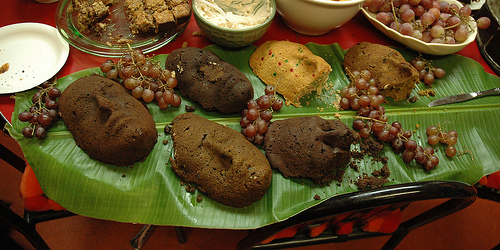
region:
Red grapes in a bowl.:
[377, 0, 489, 62]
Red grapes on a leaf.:
[350, 92, 498, 188]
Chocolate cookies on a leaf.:
[266, 110, 355, 205]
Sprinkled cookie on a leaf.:
[236, 30, 351, 114]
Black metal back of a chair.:
[256, 170, 493, 247]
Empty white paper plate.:
[3, 6, 85, 140]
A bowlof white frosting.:
[181, 1, 276, 47]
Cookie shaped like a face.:
[41, 68, 169, 187]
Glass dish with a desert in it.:
[63, 0, 184, 58]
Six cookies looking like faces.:
[52, 30, 425, 231]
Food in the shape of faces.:
[14, 36, 402, 246]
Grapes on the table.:
[60, 22, 255, 159]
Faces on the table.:
[57, 37, 429, 204]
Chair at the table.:
[160, 107, 498, 241]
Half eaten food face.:
[246, 32, 363, 121]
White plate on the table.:
[0, 12, 91, 105]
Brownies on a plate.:
[51, 2, 251, 72]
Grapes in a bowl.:
[365, 7, 471, 72]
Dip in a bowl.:
[187, 3, 300, 42]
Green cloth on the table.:
[1, 64, 498, 246]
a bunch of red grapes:
[341, 71, 406, 136]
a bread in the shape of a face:
[269, 119, 354, 181]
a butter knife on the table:
[426, 86, 498, 109]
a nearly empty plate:
[0, 22, 71, 94]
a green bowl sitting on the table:
[192, 1, 278, 47]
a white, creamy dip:
[196, 0, 273, 27]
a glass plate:
[54, 0, 191, 57]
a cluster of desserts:
[123, 0, 193, 39]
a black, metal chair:
[239, 180, 476, 249]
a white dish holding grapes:
[361, 0, 481, 57]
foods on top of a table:
[23, 5, 473, 210]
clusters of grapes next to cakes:
[42, 55, 332, 150]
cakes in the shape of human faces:
[65, 37, 351, 192]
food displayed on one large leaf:
[31, 32, 476, 197]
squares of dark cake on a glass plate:
[65, 0, 185, 52]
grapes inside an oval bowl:
[365, 1, 480, 48]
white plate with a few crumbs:
[0, 2, 75, 97]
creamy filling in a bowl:
[190, 1, 280, 48]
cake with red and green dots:
[250, 36, 326, 93]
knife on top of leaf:
[388, 80, 496, 115]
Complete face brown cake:
[49, 75, 167, 168]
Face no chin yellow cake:
[250, 37, 345, 107]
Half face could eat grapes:
[265, 92, 475, 195]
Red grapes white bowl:
[359, 0, 493, 49]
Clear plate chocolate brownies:
[58, 1, 194, 54]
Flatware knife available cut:
[421, 86, 499, 107]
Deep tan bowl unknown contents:
[278, 0, 365, 40]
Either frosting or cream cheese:
[194, 0, 289, 49]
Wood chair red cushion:
[0, 109, 76, 249]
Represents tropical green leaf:
[17, 33, 499, 231]